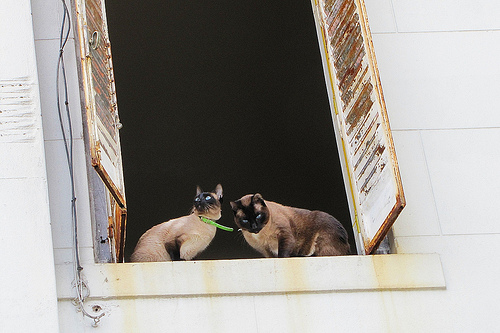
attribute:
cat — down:
[230, 194, 348, 254]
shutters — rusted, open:
[335, 42, 375, 171]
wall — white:
[429, 134, 480, 213]